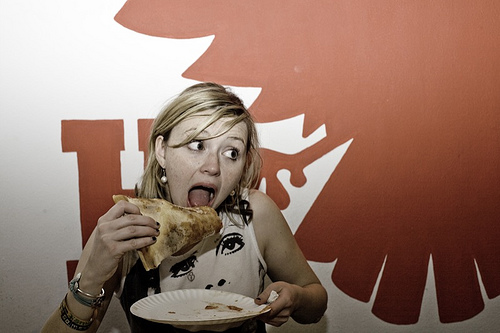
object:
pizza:
[108, 195, 232, 271]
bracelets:
[58, 298, 95, 331]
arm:
[42, 221, 121, 329]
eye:
[214, 232, 246, 257]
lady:
[40, 76, 327, 331]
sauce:
[223, 301, 247, 318]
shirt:
[107, 187, 287, 331]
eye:
[172, 257, 194, 277]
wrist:
[68, 275, 115, 295]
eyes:
[178, 127, 250, 159]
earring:
[161, 164, 168, 187]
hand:
[85, 198, 160, 283]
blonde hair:
[150, 82, 277, 112]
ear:
[153, 133, 165, 169]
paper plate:
[128, 285, 270, 325]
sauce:
[204, 300, 248, 315]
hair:
[133, 81, 266, 205]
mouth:
[180, 181, 222, 208]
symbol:
[60, 1, 498, 325]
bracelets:
[51, 265, 107, 333]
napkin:
[264, 292, 275, 299]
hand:
[256, 271, 302, 326]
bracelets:
[66, 271, 115, 310]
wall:
[2, 5, 500, 325]